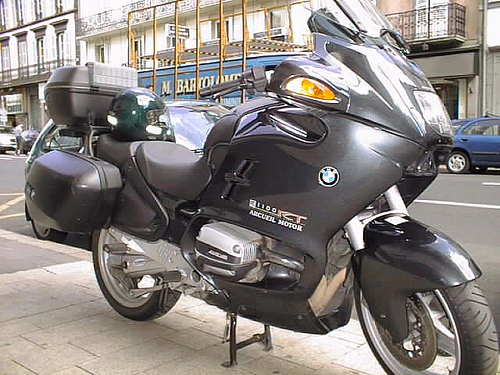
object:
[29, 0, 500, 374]
motorcycle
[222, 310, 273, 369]
kickstand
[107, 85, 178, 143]
helmet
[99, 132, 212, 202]
seat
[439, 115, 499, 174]
car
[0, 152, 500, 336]
road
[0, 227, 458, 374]
sidewalk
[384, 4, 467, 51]
balcony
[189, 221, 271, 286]
engine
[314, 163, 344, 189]
insignia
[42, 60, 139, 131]
storage compartment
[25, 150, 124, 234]
storage compartment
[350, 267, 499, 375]
wheel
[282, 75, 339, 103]
light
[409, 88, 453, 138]
headlight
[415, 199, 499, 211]
line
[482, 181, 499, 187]
line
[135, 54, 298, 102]
sign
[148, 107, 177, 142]
face mask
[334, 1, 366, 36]
wiper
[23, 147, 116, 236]
car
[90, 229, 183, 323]
wheel